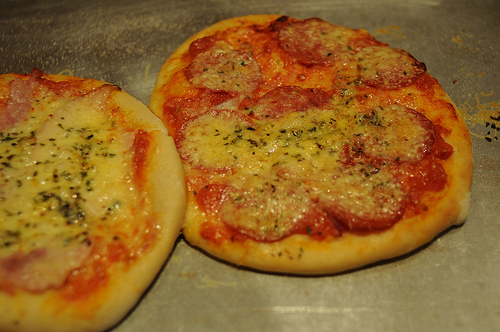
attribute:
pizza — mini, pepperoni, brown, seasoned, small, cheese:
[145, 21, 494, 277]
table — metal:
[0, 10, 498, 328]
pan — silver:
[127, 32, 385, 222]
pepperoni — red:
[198, 46, 258, 90]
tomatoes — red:
[193, 33, 236, 53]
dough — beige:
[144, 50, 201, 266]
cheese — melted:
[188, 100, 270, 166]